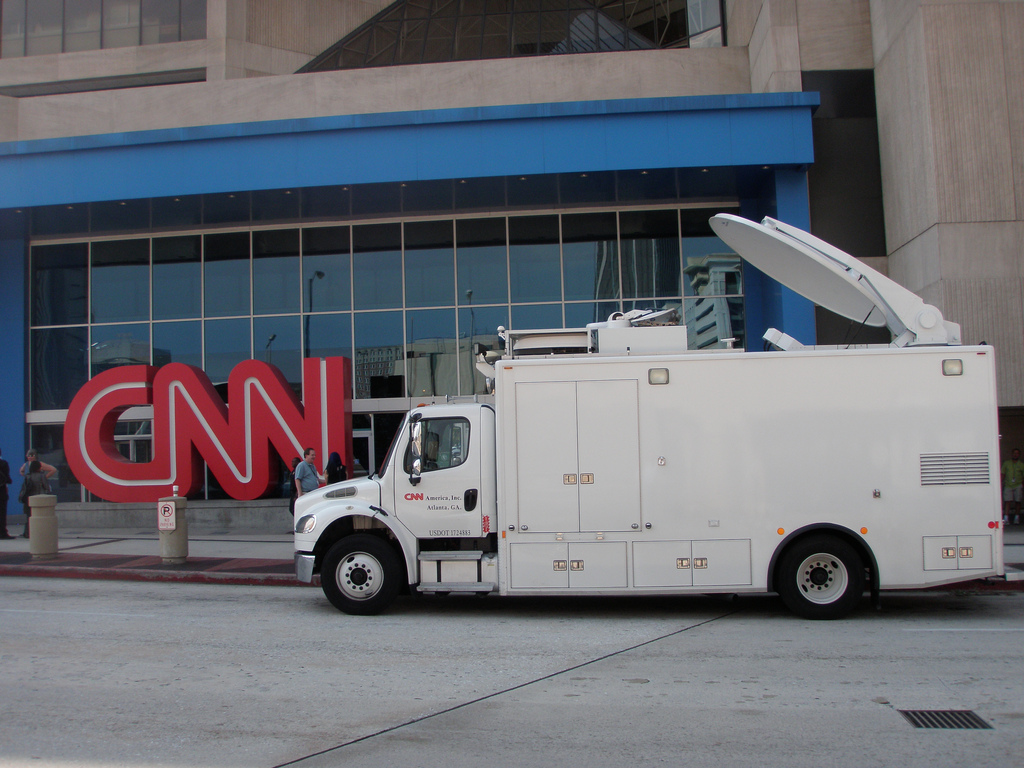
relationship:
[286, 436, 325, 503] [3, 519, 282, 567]
man on pavement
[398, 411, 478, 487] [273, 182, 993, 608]
window in truck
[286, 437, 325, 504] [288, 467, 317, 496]
man in a shirt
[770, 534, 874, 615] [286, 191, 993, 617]
tire of van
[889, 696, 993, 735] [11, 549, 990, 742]
grate on street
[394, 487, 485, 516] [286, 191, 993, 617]
sticker on van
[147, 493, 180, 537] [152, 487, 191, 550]
sign on post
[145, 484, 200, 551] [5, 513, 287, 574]
post on sidewalk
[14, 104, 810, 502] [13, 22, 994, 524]
area of a building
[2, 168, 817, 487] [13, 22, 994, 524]
entrance of a building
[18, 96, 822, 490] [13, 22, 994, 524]
entrance of building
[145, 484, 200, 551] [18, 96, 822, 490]
post outside entrance